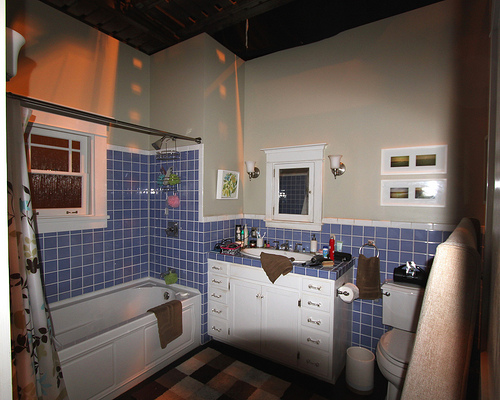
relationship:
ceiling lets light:
[6, 1, 497, 69] [32, 18, 275, 186]